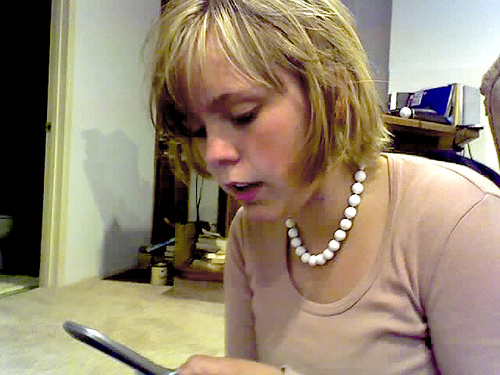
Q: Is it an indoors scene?
A: Yes, it is indoors.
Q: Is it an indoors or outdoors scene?
A: It is indoors.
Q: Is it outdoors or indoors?
A: It is indoors.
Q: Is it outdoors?
A: No, it is indoors.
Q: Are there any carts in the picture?
A: No, there are no carts.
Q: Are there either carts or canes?
A: No, there are no carts or canes.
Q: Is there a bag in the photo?
A: No, there are no bags.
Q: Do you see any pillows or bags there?
A: No, there are no bags or pillows.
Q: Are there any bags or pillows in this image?
A: No, there are no bags or pillows.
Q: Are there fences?
A: No, there are no fences.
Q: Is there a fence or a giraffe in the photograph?
A: No, there are no fences or giraffes.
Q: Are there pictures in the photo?
A: No, there are no pictures.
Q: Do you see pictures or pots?
A: No, there are no pictures or pots.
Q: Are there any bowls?
A: No, there are no bowls.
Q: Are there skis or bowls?
A: No, there are no bowls or skis.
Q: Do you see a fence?
A: No, there are no fences.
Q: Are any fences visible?
A: No, there are no fences.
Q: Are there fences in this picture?
A: No, there are no fences.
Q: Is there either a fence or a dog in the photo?
A: No, there are no fences or dogs.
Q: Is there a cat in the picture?
A: No, there are no cats.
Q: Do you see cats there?
A: No, there are no cats.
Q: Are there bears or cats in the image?
A: No, there are no cats or bears.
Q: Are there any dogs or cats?
A: No, there are no cats or dogs.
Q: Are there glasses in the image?
A: No, there are no glasses.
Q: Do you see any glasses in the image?
A: No, there are no glasses.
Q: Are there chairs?
A: No, there are no chairs.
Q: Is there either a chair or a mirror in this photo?
A: No, there are no chairs or mirrors.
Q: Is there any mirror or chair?
A: No, there are no chairs or mirrors.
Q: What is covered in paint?
A: The wall is covered in paint.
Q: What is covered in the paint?
A: The wall is covered in paint.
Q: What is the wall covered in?
A: The wall is covered in paint.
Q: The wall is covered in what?
A: The wall is covered in paint.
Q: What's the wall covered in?
A: The wall is covered in paint.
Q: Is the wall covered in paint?
A: Yes, the wall is covered in paint.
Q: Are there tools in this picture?
A: No, there are no tools.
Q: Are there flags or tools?
A: No, there are no tools or flags.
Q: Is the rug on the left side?
A: Yes, the rug is on the left of the image.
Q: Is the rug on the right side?
A: No, the rug is on the left of the image.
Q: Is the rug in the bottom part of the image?
A: Yes, the rug is in the bottom of the image.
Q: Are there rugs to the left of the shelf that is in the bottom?
A: Yes, there is a rug to the left of the shelf.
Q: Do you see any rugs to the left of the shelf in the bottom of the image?
A: Yes, there is a rug to the left of the shelf.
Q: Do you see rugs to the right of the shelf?
A: No, the rug is to the left of the shelf.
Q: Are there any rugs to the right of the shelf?
A: No, the rug is to the left of the shelf.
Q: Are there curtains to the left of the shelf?
A: No, there is a rug to the left of the shelf.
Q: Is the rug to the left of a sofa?
A: No, the rug is to the left of a shelf.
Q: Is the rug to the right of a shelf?
A: No, the rug is to the left of a shelf.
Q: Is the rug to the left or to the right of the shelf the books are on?
A: The rug is to the left of the shelf.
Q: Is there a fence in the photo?
A: No, there are no fences.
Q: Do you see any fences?
A: No, there are no fences.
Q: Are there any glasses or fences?
A: No, there are no fences or glasses.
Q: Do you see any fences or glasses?
A: No, there are no fences or glasses.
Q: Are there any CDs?
A: No, there are no cds.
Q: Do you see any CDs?
A: No, there are no cds.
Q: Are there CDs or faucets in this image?
A: No, there are no CDs or faucets.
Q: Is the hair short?
A: Yes, the hair is short.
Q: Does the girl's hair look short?
A: Yes, the hair is short.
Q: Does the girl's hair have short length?
A: Yes, the hair is short.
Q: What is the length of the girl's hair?
A: The hair is short.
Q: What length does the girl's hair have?
A: The hair has short length.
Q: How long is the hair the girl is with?
A: The hair is short.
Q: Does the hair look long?
A: No, the hair is short.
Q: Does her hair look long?
A: No, the hair is short.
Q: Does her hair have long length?
A: No, the hair is short.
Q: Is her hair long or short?
A: The hair is short.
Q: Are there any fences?
A: No, there are no fences.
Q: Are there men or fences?
A: No, there are no fences or men.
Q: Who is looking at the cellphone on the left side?
A: The girl is looking at the cellphone.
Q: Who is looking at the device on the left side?
A: The girl is looking at the cellphone.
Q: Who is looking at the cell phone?
A: The girl is looking at the cellphone.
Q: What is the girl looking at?
A: The girl is looking at the mobile phone.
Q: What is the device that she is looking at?
A: The device is a cell phone.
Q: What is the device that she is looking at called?
A: The device is a cell phone.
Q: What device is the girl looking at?
A: The girl is looking at the cell phone.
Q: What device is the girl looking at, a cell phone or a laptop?
A: The girl is looking at a cell phone.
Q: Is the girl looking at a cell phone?
A: Yes, the girl is looking at a cell phone.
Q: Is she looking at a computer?
A: No, the girl is looking at a cell phone.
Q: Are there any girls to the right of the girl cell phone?
A: Yes, there is a girl to the right of the mobile phone.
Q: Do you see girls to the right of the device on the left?
A: Yes, there is a girl to the right of the mobile phone.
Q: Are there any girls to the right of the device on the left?
A: Yes, there is a girl to the right of the mobile phone.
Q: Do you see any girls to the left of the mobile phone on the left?
A: No, the girl is to the right of the mobile phone.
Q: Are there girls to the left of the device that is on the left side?
A: No, the girl is to the right of the mobile phone.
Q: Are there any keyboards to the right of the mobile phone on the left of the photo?
A: No, there is a girl to the right of the mobile phone.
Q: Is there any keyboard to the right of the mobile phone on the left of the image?
A: No, there is a girl to the right of the mobile phone.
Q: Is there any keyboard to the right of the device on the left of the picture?
A: No, there is a girl to the right of the mobile phone.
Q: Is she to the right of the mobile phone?
A: Yes, the girl is to the right of the mobile phone.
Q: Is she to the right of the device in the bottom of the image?
A: Yes, the girl is to the right of the mobile phone.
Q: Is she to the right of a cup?
A: No, the girl is to the right of the mobile phone.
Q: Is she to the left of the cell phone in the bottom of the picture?
A: No, the girl is to the right of the mobile phone.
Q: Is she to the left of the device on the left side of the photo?
A: No, the girl is to the right of the mobile phone.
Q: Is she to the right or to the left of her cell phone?
A: The girl is to the right of the cellphone.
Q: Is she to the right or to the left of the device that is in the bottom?
A: The girl is to the right of the cellphone.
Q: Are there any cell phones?
A: Yes, there is a cell phone.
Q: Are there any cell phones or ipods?
A: Yes, there is a cell phone.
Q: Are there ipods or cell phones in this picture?
A: Yes, there is a cell phone.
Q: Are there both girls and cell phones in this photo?
A: Yes, there are both a cell phone and a girl.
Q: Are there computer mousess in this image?
A: No, there are no computer mousess.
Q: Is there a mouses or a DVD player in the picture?
A: No, there are no computer mousess or DVD players.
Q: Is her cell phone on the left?
A: Yes, the mobile phone is on the left of the image.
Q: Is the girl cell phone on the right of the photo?
A: No, the cell phone is on the left of the image.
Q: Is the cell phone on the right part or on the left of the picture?
A: The cell phone is on the left of the image.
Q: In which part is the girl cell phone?
A: The mobile phone is on the left of the image.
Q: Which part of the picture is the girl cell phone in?
A: The mobile phone is on the left of the image.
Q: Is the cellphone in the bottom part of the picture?
A: Yes, the cellphone is in the bottom of the image.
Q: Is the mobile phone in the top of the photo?
A: No, the mobile phone is in the bottom of the image.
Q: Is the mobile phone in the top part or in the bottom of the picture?
A: The mobile phone is in the bottom of the image.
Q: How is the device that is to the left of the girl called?
A: The device is a cell phone.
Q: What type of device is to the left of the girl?
A: The device is a cell phone.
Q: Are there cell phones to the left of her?
A: Yes, there is a cell phone to the left of the girl.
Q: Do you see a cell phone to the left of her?
A: Yes, there is a cell phone to the left of the girl.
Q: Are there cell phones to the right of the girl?
A: No, the cell phone is to the left of the girl.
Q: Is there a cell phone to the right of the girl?
A: No, the cell phone is to the left of the girl.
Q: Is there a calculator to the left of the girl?
A: No, there is a cell phone to the left of the girl.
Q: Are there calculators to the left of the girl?
A: No, there is a cell phone to the left of the girl.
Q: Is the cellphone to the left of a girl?
A: Yes, the cellphone is to the left of a girl.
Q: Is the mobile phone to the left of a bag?
A: No, the mobile phone is to the left of a girl.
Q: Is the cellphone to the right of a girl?
A: No, the cellphone is to the left of a girl.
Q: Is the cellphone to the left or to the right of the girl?
A: The cellphone is to the left of the girl.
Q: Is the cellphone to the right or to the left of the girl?
A: The cellphone is to the left of the girl.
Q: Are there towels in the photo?
A: No, there are no towels.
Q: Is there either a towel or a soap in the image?
A: No, there are no towels or soaps.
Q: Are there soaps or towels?
A: No, there are no towels or soaps.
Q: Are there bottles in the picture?
A: No, there are no bottles.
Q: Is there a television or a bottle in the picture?
A: No, there are no bottles or televisions.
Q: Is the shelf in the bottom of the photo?
A: Yes, the shelf is in the bottom of the image.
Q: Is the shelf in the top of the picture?
A: No, the shelf is in the bottom of the image.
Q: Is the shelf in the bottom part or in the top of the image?
A: The shelf is in the bottom of the image.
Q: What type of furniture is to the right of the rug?
A: The piece of furniture is a shelf.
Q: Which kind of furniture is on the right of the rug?
A: The piece of furniture is a shelf.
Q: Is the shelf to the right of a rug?
A: Yes, the shelf is to the right of a rug.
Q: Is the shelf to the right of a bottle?
A: No, the shelf is to the right of a rug.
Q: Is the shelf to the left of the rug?
A: No, the shelf is to the right of the rug.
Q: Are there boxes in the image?
A: No, there are no boxes.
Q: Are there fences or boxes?
A: No, there are no boxes or fences.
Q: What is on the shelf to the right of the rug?
A: The books are on the shelf.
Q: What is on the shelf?
A: The books are on the shelf.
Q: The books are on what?
A: The books are on the shelf.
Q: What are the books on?
A: The books are on the shelf.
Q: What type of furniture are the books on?
A: The books are on the shelf.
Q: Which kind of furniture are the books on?
A: The books are on the shelf.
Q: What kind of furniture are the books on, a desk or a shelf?
A: The books are on a shelf.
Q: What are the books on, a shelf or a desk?
A: The books are on a shelf.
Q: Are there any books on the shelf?
A: Yes, there are books on the shelf.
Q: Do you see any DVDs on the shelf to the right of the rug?
A: No, there are books on the shelf.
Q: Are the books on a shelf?
A: Yes, the books are on a shelf.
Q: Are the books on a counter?
A: No, the books are on a shelf.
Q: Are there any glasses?
A: No, there are no glasses.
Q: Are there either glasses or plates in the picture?
A: No, there are no glasses or plates.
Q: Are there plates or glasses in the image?
A: No, there are no glasses or plates.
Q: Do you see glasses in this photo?
A: No, there are no glasses.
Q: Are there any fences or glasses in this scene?
A: No, there are no glasses or fences.